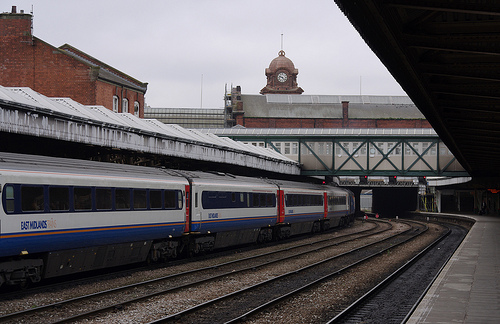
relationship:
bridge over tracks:
[217, 132, 468, 176] [300, 226, 410, 319]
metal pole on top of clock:
[278, 21, 286, 61] [275, 70, 287, 86]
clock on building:
[276, 71, 291, 84] [218, 51, 445, 152]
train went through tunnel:
[0, 149, 361, 293] [332, 182, 419, 221]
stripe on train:
[1, 200, 363, 238] [40, 101, 370, 322]